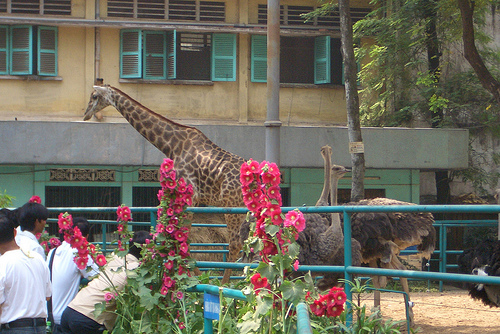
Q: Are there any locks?
A: No, there are no locks.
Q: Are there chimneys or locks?
A: No, there are no locks or chimneys.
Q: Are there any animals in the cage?
A: Yes, there are animals in the cage.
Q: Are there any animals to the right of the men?
A: Yes, there are animals to the right of the men.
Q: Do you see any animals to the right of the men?
A: Yes, there are animals to the right of the men.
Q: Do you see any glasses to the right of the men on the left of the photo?
A: No, there are animals to the right of the men.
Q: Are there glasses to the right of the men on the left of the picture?
A: No, there are animals to the right of the men.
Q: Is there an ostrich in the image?
A: Yes, there are ostriches.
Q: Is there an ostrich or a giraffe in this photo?
A: Yes, there are ostriches.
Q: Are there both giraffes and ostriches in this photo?
A: Yes, there are both ostriches and a giraffe.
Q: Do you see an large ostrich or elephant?
A: Yes, there are large ostriches.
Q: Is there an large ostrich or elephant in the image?
A: Yes, there are large ostriches.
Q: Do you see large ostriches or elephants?
A: Yes, there are large ostriches.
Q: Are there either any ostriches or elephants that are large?
A: Yes, the ostriches are large.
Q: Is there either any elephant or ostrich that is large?
A: Yes, the ostriches are large.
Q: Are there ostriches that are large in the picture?
A: Yes, there are large ostriches.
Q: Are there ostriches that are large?
A: Yes, there are ostriches that are large.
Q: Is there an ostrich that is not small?
A: Yes, there are large ostriches.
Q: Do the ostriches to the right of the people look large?
A: Yes, the ostriches are large.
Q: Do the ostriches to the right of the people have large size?
A: Yes, the ostriches are large.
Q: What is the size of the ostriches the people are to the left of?
A: The ostriches are large.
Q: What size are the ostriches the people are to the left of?
A: The ostriches are large.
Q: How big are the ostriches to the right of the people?
A: The ostriches are large.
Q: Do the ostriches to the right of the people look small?
A: No, the ostriches are large.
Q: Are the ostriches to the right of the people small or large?
A: The ostriches are large.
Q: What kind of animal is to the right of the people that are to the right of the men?
A: The animals are ostriches.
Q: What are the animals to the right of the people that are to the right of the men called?
A: The animals are ostriches.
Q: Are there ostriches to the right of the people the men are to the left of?
A: Yes, there are ostriches to the right of the people.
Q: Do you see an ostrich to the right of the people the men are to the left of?
A: Yes, there are ostriches to the right of the people.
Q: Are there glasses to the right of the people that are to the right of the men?
A: No, there are ostriches to the right of the people.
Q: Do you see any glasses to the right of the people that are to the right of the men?
A: No, there are ostriches to the right of the people.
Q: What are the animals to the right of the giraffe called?
A: The animals are ostriches.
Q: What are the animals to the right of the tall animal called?
A: The animals are ostriches.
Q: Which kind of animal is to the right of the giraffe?
A: The animals are ostriches.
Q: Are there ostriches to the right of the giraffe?
A: Yes, there are ostriches to the right of the giraffe.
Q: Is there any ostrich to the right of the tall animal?
A: Yes, there are ostriches to the right of the giraffe.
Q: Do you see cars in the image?
A: No, there are no cars.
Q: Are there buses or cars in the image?
A: No, there are no cars or buses.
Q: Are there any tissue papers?
A: No, there are no tissue papers.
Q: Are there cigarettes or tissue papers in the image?
A: No, there are no tissue papers or cigarettes.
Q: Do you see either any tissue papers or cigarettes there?
A: No, there are no tissue papers or cigarettes.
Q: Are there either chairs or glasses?
A: No, there are no glasses or chairs.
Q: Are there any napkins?
A: No, there are no napkins.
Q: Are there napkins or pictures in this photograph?
A: No, there are no napkins or pictures.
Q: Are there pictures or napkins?
A: No, there are no napkins or pictures.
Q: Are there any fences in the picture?
A: Yes, there is a fence.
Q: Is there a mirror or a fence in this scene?
A: Yes, there is a fence.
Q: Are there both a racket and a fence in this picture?
A: No, there is a fence but no rackets.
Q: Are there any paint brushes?
A: No, there are no paint brushes.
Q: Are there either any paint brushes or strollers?
A: No, there are no paint brushes or strollers.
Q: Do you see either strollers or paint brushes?
A: No, there are no paint brushes or strollers.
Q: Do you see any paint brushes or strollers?
A: No, there are no paint brushes or strollers.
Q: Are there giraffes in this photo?
A: Yes, there is a giraffe.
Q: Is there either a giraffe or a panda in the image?
A: Yes, there is a giraffe.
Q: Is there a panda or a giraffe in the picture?
A: Yes, there is a giraffe.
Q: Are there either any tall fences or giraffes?
A: Yes, there is a tall giraffe.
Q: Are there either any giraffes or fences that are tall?
A: Yes, the giraffe is tall.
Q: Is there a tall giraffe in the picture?
A: Yes, there is a tall giraffe.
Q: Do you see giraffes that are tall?
A: Yes, there is a tall giraffe.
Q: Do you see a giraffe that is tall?
A: Yes, there is a giraffe that is tall.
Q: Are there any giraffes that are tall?
A: Yes, there is a giraffe that is tall.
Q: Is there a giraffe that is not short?
A: Yes, there is a tall giraffe.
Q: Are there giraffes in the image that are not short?
A: Yes, there is a tall giraffe.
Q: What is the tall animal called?
A: The animal is a giraffe.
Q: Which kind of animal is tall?
A: The animal is a giraffe.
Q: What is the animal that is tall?
A: The animal is a giraffe.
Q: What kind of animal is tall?
A: The animal is a giraffe.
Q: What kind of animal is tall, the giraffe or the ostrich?
A: The giraffe is tall.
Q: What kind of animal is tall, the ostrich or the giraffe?
A: The giraffe is tall.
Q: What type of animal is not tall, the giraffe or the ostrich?
A: The ostrich is not tall.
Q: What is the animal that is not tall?
A: The animal is an ostrich.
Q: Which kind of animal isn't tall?
A: The animal is an ostrich.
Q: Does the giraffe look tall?
A: Yes, the giraffe is tall.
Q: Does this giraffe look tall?
A: Yes, the giraffe is tall.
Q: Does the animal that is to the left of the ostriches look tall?
A: Yes, the giraffe is tall.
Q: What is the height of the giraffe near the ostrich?
A: The giraffe is tall.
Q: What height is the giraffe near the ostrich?
A: The giraffe is tall.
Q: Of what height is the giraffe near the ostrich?
A: The giraffe is tall.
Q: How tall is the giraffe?
A: The giraffe is tall.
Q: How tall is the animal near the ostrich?
A: The giraffe is tall.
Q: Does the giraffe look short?
A: No, the giraffe is tall.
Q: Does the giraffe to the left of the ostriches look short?
A: No, the giraffe is tall.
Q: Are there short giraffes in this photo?
A: No, there is a giraffe but it is tall.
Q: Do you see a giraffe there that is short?
A: No, there is a giraffe but it is tall.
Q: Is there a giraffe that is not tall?
A: No, there is a giraffe but it is tall.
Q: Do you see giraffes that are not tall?
A: No, there is a giraffe but it is tall.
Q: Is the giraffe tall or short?
A: The giraffe is tall.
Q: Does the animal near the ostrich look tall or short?
A: The giraffe is tall.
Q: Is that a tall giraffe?
A: Yes, that is a tall giraffe.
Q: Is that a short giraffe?
A: No, that is a tall giraffe.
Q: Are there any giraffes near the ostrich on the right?
A: Yes, there is a giraffe near the ostrich.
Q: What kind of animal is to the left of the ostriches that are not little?
A: The animal is a giraffe.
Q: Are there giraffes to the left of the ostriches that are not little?
A: Yes, there is a giraffe to the left of the ostriches.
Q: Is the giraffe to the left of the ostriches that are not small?
A: Yes, the giraffe is to the left of the ostriches.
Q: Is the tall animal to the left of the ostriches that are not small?
A: Yes, the giraffe is to the left of the ostriches.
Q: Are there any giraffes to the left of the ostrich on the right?
A: Yes, there is a giraffe to the left of the ostrich.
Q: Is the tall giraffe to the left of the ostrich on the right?
A: Yes, the giraffe is to the left of the ostrich.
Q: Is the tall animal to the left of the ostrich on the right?
A: Yes, the giraffe is to the left of the ostrich.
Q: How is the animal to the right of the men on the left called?
A: The animal is a giraffe.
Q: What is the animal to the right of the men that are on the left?
A: The animal is a giraffe.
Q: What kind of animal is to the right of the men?
A: The animal is a giraffe.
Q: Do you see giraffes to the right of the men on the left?
A: Yes, there is a giraffe to the right of the men.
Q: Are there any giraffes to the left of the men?
A: No, the giraffe is to the right of the men.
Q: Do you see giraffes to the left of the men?
A: No, the giraffe is to the right of the men.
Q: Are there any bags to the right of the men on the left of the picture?
A: No, there is a giraffe to the right of the men.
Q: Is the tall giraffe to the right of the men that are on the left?
A: Yes, the giraffe is to the right of the men.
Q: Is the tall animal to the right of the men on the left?
A: Yes, the giraffe is to the right of the men.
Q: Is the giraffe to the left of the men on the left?
A: No, the giraffe is to the right of the men.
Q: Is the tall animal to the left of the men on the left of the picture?
A: No, the giraffe is to the right of the men.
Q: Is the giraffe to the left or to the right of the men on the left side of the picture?
A: The giraffe is to the right of the men.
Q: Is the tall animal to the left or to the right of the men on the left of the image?
A: The giraffe is to the right of the men.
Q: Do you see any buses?
A: No, there are no buses.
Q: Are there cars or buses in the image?
A: No, there are no buses or cars.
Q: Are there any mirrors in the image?
A: No, there are no mirrors.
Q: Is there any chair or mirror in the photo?
A: No, there are no mirrors or chairs.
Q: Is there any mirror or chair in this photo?
A: No, there are no mirrors or chairs.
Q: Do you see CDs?
A: No, there are no cds.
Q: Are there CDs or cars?
A: No, there are no CDs or cars.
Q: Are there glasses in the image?
A: No, there are no glasses.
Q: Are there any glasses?
A: No, there are no glasses.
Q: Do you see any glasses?
A: No, there are no glasses.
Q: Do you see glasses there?
A: No, there are no glasses.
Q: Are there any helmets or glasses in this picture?
A: No, there are no glasses or helmets.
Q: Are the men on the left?
A: Yes, the men are on the left of the image.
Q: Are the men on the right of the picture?
A: No, the men are on the left of the image.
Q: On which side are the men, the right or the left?
A: The men are on the left of the image.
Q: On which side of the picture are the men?
A: The men are on the left of the image.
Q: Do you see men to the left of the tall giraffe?
A: Yes, there are men to the left of the giraffe.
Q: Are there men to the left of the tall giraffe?
A: Yes, there are men to the left of the giraffe.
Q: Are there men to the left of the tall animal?
A: Yes, there are men to the left of the giraffe.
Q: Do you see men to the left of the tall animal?
A: Yes, there are men to the left of the giraffe.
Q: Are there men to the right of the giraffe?
A: No, the men are to the left of the giraffe.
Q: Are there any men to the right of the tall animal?
A: No, the men are to the left of the giraffe.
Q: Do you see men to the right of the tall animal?
A: No, the men are to the left of the giraffe.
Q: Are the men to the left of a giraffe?
A: Yes, the men are to the left of a giraffe.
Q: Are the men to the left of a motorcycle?
A: No, the men are to the left of a giraffe.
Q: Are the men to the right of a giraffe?
A: No, the men are to the left of a giraffe.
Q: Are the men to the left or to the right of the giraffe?
A: The men are to the left of the giraffe.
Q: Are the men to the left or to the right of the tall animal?
A: The men are to the left of the giraffe.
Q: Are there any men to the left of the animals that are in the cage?
A: Yes, there are men to the left of the animals.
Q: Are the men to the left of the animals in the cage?
A: Yes, the men are to the left of the animals.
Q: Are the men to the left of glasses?
A: No, the men are to the left of the animals.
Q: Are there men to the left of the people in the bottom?
A: Yes, there are men to the left of the people.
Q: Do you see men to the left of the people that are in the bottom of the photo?
A: Yes, there are men to the left of the people.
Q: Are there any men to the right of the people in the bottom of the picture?
A: No, the men are to the left of the people.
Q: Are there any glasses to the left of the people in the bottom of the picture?
A: No, there are men to the left of the people.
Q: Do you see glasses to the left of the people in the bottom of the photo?
A: No, there are men to the left of the people.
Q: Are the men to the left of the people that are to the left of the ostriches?
A: Yes, the men are to the left of the people.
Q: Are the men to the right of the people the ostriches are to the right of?
A: No, the men are to the left of the people.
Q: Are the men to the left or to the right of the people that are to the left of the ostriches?
A: The men are to the left of the people.